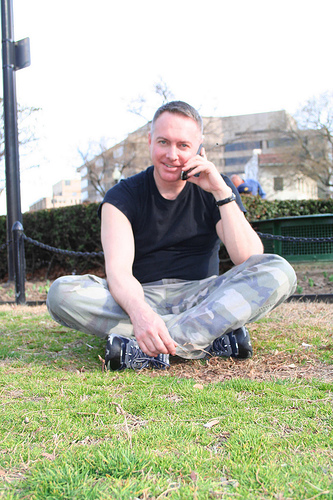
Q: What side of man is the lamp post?
A: The man's right side.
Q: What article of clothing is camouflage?
A: The man's pants.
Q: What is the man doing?
A: Talking on the phone.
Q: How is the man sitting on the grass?
A: He is sitting cross legged.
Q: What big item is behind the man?
A: A building.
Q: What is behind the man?
A: Shrubs.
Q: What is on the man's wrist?
A: A watch.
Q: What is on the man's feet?
A: Sneakers.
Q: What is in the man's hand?
A: A cellphone.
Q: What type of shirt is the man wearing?
A: Black.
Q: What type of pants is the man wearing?
A: Camouflage.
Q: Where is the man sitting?
A: On the ground.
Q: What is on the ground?
A: Grass.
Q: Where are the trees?
A: In front of the building.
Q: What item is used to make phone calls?
A: A cell phone.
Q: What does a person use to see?
A: Eyes.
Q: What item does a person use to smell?
A: A nose.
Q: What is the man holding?
A: A cell phone.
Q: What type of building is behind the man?
A: A apartment building.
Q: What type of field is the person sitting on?
A: The grass.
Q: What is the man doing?
A: Talking on a cell phone.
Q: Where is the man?
A: In the grass.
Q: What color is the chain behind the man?
A: Black.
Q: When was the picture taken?
A: Daytime.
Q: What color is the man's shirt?
A: Black.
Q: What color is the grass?
A: Green.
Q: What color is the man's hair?
A: Brown.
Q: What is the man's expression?
A: Smiling.